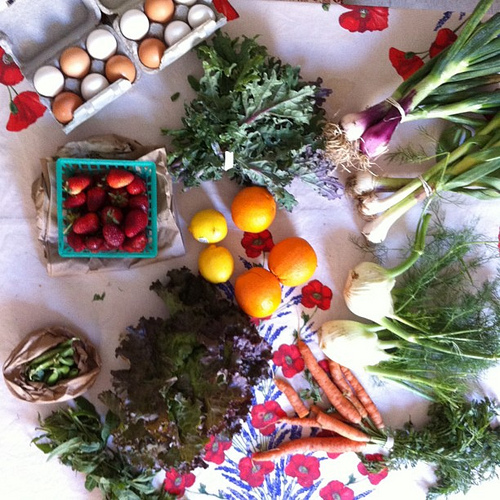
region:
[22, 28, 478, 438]
food items seen from above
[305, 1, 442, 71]
white tablecloth with a floral pattern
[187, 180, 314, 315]
two lemons and three oranges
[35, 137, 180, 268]
basket of strawberries on folded paper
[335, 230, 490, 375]
two pieces of fennel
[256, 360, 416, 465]
a bunch of carrots, one of them broken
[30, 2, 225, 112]
an open carton of eggs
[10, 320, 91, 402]
some green beans on a piece of paper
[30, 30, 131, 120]
brown and white eggs, three of each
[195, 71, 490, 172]
green vegetables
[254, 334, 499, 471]
A bunch of carrots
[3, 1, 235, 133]
Two cartons of eggs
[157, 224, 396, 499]
A flower pattern on the tablecloth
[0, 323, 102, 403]
A brown bag of peas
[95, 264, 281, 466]
Green and purple lettuce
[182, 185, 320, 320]
Three oranges and two lemons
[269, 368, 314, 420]
A broken part of carrot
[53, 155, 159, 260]
A green box with strawberries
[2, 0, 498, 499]
Produce on a white, red, and blue tablecloth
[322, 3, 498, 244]
Two bunches of green onions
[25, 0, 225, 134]
a dozen eggs in two cartons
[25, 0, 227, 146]
seven white and five brown eggs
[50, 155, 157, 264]
a scant pint of strawberries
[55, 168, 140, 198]
under ripe strawberries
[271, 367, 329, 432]
a broken piece of carrot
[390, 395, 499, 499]
carrot tops not a comedian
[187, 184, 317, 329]
citrus fruit in the center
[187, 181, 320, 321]
two fruits of the same genus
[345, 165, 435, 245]
small bunch of green onions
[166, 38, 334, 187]
a small bunch of greens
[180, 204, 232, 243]
Bright yellow fruit on table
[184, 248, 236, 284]
Bright yellow fruit on table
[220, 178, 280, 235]
Bright orange fruit on table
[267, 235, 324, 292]
Bright orange fruit on table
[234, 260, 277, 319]
Bright orange fruit on table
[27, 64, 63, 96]
White egg in carton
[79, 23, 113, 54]
White egg in carton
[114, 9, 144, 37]
White egg in carton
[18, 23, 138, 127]
Brown and white eggs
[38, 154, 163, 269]
Red strawberrys in green container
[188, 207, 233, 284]
Two yellow lemons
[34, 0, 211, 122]
Dozen of white and brown eggs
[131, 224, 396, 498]
Red poppy flower pattern on a cloth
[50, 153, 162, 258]
Blue basket full of strawberries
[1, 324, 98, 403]
Beans in a paper bag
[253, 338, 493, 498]
Six orange carrots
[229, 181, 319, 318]
Three oranges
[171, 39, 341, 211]
Leafy greens in a bundle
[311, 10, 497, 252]
Two types of onions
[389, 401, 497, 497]
Leafy green carrot tops